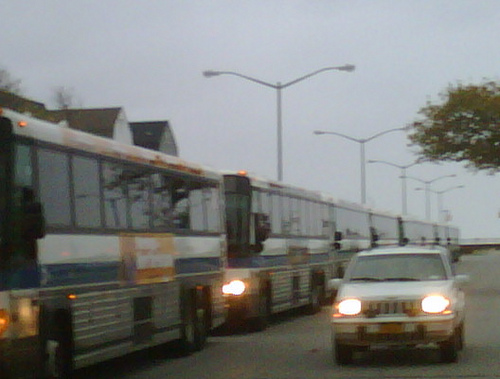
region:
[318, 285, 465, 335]
The vehicle's headlights are on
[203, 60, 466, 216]
A row of streetlights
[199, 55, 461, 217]
The streetlights are not turned on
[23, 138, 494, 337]
Eight buses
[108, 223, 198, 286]
An ad on the side of the bus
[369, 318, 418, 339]
A yellow license plate on the white vehicle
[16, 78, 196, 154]
Homes on the other side of the buses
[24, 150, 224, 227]
Windows along the side of the bus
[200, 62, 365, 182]
THIS IS A LIGHT POLE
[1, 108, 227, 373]
THIS IS A BUS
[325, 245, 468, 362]
THIS IS A WHITE TRUCK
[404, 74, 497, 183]
THIS IS A GREEN TREE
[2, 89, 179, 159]
THESE ARE THREE BUILDINGS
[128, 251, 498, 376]
THIS IS A SIDEWALK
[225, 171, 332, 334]
THIS IS A SECOND BUS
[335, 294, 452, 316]
THESE ARE THE HEADLIGHTS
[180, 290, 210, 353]
THIS IS A TIRE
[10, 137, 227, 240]
THESE ARE THE WINDOWS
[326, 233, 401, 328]
white car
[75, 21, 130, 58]
white clouds in blue sky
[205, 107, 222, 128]
white clouds in blue sky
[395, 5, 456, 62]
white clouds in blue sky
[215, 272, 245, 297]
bus light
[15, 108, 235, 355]
white and gray passenger bus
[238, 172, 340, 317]
white and gray passenger bus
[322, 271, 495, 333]
the headlights of a car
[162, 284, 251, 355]
the wheels of a bus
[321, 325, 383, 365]
the wheels of a car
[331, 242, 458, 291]
the winshield of a car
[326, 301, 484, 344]
the bumper of a car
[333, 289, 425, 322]
the grill of a car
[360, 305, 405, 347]
the license plate of a car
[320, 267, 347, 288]
the mirror of a car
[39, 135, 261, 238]
the windows on a bus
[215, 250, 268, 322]
the head light on a bus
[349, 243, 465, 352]
white car on road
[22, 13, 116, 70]
white clouds in blue sky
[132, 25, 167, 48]
white clouds in blue sky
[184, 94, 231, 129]
white clouds in blue sky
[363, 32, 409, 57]
white clouds in blue sky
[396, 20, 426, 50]
white clouds in blue sky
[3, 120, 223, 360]
white and gray passenger bus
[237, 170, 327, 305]
white and gray passenger bus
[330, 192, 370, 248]
white and gray passenger bus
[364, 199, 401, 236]
white and gray passenger bus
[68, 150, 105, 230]
a window on a bus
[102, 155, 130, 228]
a window on a bus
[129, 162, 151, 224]
a window on a bus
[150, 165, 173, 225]
a window on a bus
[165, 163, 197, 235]
a window on a bus